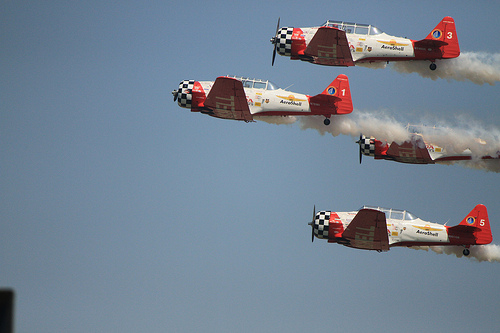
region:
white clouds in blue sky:
[18, 23, 51, 67]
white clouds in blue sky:
[81, 4, 127, 54]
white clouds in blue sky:
[30, 116, 70, 158]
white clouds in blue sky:
[106, 167, 161, 205]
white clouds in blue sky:
[193, 161, 246, 215]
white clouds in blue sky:
[72, 191, 137, 254]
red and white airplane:
[157, 66, 352, 136]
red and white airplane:
[300, 187, 481, 268]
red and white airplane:
[271, 17, 471, 73]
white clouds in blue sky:
[181, 240, 231, 261]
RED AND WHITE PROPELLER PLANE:
[162, 70, 344, 127]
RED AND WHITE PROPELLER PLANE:
[298, 205, 485, 259]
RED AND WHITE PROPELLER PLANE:
[361, 99, 493, 155]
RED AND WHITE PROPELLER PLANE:
[280, 19, 497, 85]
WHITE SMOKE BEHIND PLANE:
[332, 111, 497, 152]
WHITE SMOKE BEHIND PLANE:
[404, 59, 499, 85]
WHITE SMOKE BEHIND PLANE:
[409, 226, 496, 271]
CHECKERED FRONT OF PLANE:
[297, 202, 323, 246]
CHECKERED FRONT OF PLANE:
[170, 71, 215, 111]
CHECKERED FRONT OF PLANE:
[269, 23, 296, 52]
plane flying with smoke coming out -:
[131, 4, 498, 263]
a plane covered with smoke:
[353, 120, 499, 172]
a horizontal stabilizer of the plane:
[454, 220, 482, 235]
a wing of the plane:
[343, 204, 390, 244]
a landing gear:
[459, 248, 471, 257]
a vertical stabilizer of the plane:
[459, 200, 494, 225]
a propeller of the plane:
[303, 203, 320, 245]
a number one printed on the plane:
[338, 85, 347, 97]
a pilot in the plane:
[327, 20, 340, 29]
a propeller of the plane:
[266, 13, 288, 69]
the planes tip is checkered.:
[173, 71, 212, 121]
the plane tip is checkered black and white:
[115, 63, 219, 165]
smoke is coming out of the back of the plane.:
[348, 96, 498, 198]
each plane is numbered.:
[288, 81, 376, 139]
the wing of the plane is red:
[178, 65, 383, 185]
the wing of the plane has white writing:
[164, 64, 269, 159]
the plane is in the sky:
[176, 65, 406, 136]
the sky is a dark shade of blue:
[146, 248, 272, 321]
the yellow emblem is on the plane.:
[382, 208, 489, 275]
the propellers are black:
[289, 195, 339, 257]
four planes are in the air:
[245, 13, 442, 260]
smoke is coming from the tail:
[411, 225, 482, 279]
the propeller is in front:
[292, 185, 339, 242]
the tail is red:
[446, 208, 491, 241]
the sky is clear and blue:
[88, 212, 266, 308]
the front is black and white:
[310, 177, 367, 244]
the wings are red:
[325, 195, 411, 283]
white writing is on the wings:
[189, 73, 276, 138]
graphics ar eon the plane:
[375, 35, 427, 58]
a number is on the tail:
[440, 19, 465, 74]